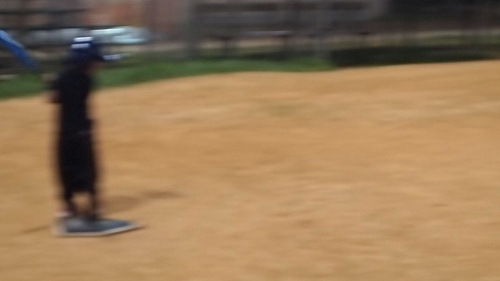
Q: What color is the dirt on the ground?
A: Brown.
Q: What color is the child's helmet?
A: Blue.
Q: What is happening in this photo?
A: A child is batting.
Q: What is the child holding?
A: A baseball bat.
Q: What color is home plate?
A: Blue and white.